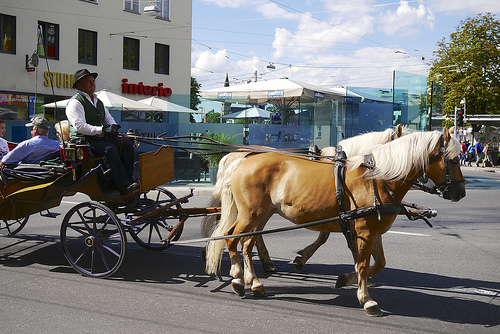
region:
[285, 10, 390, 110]
The sky is blue with clouds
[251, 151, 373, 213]
The horse is brown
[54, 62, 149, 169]
The man has a hat on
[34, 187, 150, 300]
The wheel is round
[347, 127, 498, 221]
The horse has a mane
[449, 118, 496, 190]
People are walking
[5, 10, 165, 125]
The building has windows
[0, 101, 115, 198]
People are in the back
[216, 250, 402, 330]
The horses are walking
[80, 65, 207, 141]
Umbrellas are up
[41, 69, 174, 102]
Signs with the names of stores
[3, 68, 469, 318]
Two horses pulling a wagon with people in it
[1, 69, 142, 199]
Three passengers and a driver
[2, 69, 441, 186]
Translucent walls around the eatery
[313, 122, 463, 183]
The horses have long manes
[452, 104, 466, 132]
Street light on a pole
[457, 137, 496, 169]
Pedestrians walking in the background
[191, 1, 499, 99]
White puffy clouds and blue sky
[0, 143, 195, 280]
Old-fashioned wooden wagon for transportation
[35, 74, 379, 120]
Numerous umbrellas to protect the patrons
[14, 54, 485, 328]
horses pulling a carriage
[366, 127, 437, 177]
blonde mane of a horse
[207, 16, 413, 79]
cloudy sky in the distance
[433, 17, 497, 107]
green leaves on trees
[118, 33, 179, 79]
windows on a building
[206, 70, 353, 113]
tent in a parking lot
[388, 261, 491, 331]
shadow casted on the ground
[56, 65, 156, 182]
driver of a carriage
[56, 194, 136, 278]
wheel of a carriage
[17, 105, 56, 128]
hat on a man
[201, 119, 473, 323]
horses on a street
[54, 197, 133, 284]
wheel on a carriage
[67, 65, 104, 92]
hat on a persons head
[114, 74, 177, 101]
red sign on a building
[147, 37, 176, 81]
window on a building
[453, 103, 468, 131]
traffic signal on a pole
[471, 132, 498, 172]
people walking on a sidewalk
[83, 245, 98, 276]
spoke on a wheel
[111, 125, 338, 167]
reins on a horse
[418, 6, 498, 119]
green tree near a street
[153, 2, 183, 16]
window of a building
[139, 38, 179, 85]
window of a building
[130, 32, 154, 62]
window of a building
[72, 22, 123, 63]
window of a building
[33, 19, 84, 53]
window of a building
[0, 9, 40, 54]
window of a building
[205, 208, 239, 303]
leg of a horse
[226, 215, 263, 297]
leg of a horse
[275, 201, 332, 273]
leg of a horse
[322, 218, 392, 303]
leg of a horse